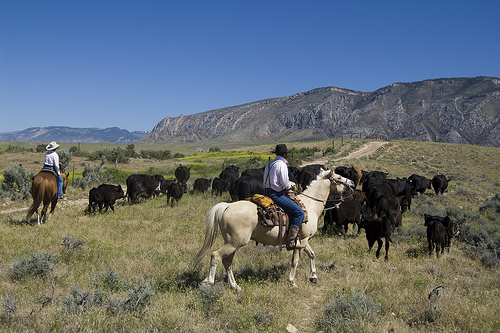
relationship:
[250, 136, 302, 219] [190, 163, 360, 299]
man rides horse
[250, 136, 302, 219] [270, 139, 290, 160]
man has hat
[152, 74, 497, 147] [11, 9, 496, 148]
mountain in background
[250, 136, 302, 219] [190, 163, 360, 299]
man on top of horse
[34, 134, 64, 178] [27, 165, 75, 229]
man on top of horse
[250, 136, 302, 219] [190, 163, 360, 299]
man on horse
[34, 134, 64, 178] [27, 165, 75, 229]
man on horse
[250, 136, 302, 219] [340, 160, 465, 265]
man rounds up animals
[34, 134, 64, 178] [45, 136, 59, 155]
man has hat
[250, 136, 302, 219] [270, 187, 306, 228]
man has jeans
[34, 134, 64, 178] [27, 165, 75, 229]
man has horse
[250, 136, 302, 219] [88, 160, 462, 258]
man herds cattle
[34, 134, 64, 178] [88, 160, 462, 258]
man herds cattle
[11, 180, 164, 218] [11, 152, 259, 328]
road through field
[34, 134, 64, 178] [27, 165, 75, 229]
man rides horse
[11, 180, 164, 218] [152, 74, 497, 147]
road leads to mountain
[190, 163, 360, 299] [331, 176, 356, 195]
horse has bridle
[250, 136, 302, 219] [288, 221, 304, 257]
man has boots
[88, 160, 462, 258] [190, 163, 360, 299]
cattle near horse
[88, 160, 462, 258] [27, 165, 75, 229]
cattle near horse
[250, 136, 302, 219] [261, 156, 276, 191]
man has suspenders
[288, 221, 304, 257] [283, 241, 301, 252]
boots in stirrup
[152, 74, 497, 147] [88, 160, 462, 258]
mountain near cattle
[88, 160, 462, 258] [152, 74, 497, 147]
cattle near mountain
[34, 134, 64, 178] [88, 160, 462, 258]
man follows cattle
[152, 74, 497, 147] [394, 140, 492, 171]
mountain has grass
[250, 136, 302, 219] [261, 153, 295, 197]
man has shirt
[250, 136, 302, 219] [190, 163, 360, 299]
man has horse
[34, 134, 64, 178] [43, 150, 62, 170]
man has shirt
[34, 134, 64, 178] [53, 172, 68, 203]
man has jeans